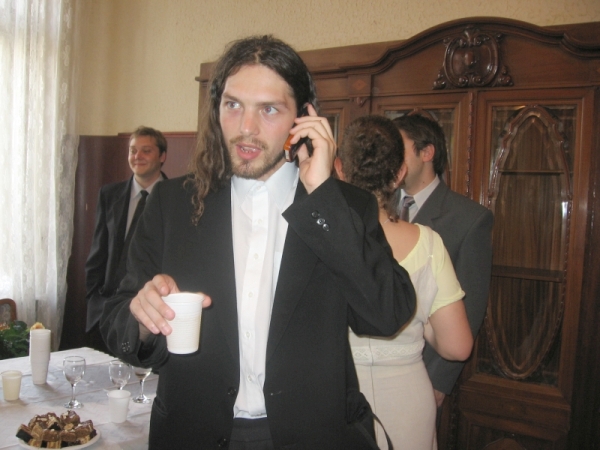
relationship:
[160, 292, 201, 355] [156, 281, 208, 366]
cup for drink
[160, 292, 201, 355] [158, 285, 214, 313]
cup for drink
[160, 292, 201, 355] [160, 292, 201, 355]
cup for cup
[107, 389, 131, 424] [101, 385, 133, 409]
drink for drink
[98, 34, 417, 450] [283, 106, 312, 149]
man talking on phone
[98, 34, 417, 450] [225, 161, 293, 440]
man wearing shirt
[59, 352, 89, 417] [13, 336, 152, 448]
glass on table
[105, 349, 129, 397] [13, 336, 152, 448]
glass on table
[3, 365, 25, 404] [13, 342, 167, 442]
cup on table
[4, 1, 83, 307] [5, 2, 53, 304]
curtain on window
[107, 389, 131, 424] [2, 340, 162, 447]
drink on table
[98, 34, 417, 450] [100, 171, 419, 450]
man wearing blazer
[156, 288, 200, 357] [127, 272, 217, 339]
cup in hand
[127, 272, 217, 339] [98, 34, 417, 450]
hand of man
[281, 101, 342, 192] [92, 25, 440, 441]
hand of man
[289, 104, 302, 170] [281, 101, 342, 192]
phone in hand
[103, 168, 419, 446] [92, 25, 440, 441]
blazer on man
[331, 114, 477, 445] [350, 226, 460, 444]
woman wearing dress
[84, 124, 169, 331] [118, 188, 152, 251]
man wearing tie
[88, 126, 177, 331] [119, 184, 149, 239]
man wearing tie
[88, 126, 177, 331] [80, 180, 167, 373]
man in suit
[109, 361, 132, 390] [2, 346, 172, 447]
glass on table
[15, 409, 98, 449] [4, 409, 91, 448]
pastries on plate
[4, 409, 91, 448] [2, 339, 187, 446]
plate on table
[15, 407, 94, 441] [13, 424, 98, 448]
pastries placed on plate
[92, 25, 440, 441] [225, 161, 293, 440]
man wearing shirt